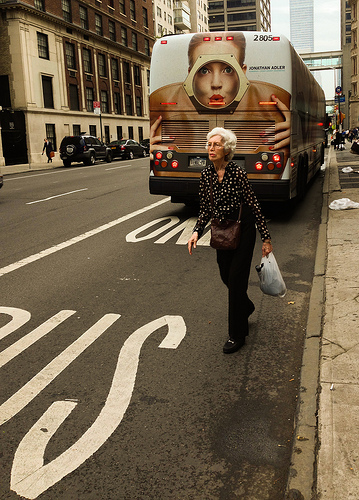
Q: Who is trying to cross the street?
A: An older woman.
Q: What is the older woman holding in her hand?
A: A shopping bag.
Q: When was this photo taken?
A: During the day.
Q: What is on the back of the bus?
A: A woman holding a handbag.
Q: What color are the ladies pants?
A: Black.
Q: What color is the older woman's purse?
A: Brown.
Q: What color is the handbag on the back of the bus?
A: Light brown.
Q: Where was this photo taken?
A: A bus stop.